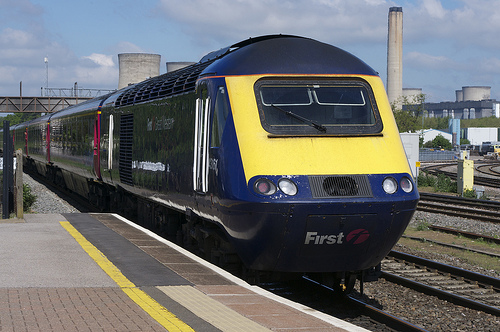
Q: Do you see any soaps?
A: No, there are no soaps.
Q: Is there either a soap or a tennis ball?
A: No, there are no soaps or tennis balls.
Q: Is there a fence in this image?
A: No, there are no fences.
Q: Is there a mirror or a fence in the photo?
A: No, there are no fences or mirrors.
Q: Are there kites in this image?
A: No, there are no kites.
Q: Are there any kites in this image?
A: No, there are no kites.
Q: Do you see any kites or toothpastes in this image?
A: No, there are no kites or toothpastes.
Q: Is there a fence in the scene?
A: No, there are no fences.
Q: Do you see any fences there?
A: No, there are no fences.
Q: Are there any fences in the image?
A: No, there are no fences.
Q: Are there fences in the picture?
A: No, there are no fences.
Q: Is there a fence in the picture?
A: No, there are no fences.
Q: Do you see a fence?
A: No, there are no fences.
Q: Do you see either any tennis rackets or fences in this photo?
A: No, there are no fences or tennis rackets.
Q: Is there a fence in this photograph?
A: No, there are no fences.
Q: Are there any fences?
A: No, there are no fences.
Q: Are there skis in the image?
A: No, there are no skis.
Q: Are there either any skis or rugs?
A: No, there are no skis or rugs.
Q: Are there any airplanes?
A: No, there are no airplanes.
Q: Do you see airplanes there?
A: No, there are no airplanes.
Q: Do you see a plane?
A: No, there are no airplanes.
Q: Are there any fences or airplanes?
A: No, there are no airplanes or fences.